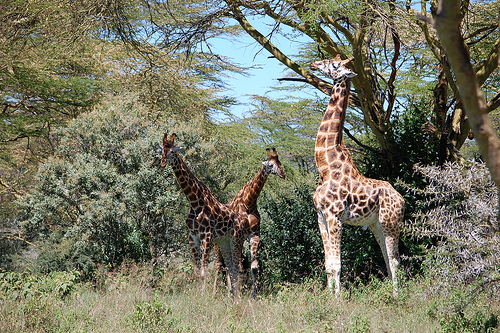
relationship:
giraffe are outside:
[266, 45, 428, 309] [94, 92, 335, 266]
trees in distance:
[0, 43, 167, 170] [44, 88, 77, 275]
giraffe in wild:
[266, 45, 428, 309] [237, 47, 498, 321]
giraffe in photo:
[266, 45, 428, 309] [237, 47, 498, 321]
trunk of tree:
[430, 30, 485, 129] [369, 13, 465, 161]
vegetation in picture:
[54, 213, 284, 316] [61, 4, 462, 310]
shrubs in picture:
[122, 214, 225, 294] [61, 4, 462, 310]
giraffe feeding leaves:
[266, 45, 428, 309] [276, 35, 319, 80]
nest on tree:
[391, 14, 444, 43] [369, 13, 465, 161]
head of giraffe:
[283, 38, 363, 98] [266, 45, 428, 309]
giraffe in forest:
[266, 45, 428, 309] [61, 4, 462, 310]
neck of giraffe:
[315, 97, 360, 147] [266, 45, 428, 309]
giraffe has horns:
[266, 45, 428, 309] [339, 45, 367, 68]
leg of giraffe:
[302, 212, 342, 295] [266, 45, 428, 309]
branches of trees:
[243, 14, 321, 70] [0, 43, 167, 170]